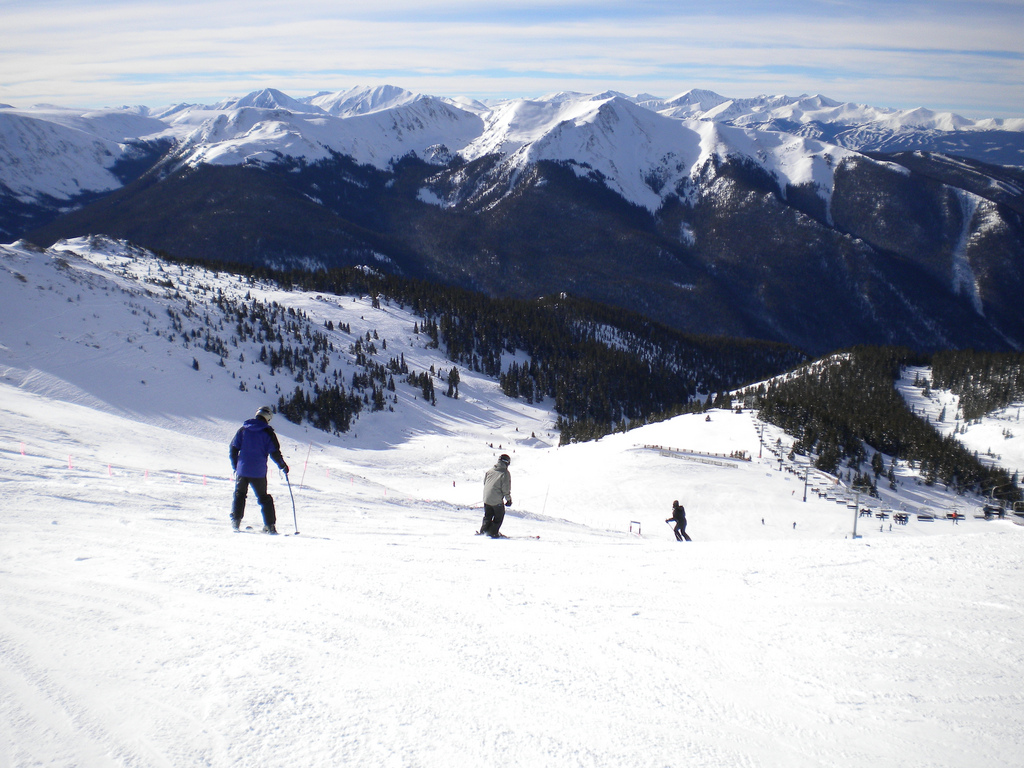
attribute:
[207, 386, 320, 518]
coat — blue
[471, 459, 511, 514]
jacket — small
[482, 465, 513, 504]
jacket — tan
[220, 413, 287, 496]
jacket — puffy, blue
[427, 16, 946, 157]
sky — hazy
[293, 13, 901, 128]
sky — cloudy, blue